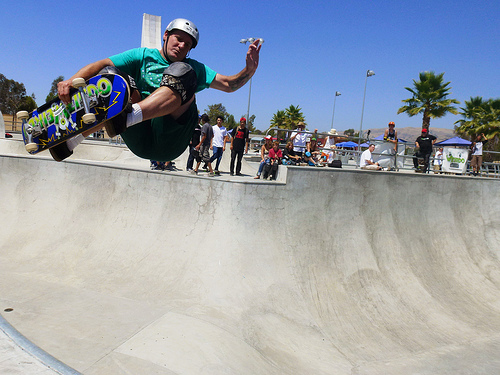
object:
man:
[47, 16, 263, 163]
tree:
[397, 68, 460, 159]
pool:
[0, 153, 497, 374]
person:
[203, 113, 230, 175]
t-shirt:
[210, 122, 228, 148]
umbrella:
[436, 136, 475, 147]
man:
[228, 115, 250, 176]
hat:
[238, 116, 244, 122]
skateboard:
[12, 71, 131, 154]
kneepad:
[158, 59, 198, 102]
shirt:
[108, 44, 216, 100]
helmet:
[163, 18, 200, 48]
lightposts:
[358, 67, 375, 136]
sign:
[440, 145, 470, 178]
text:
[445, 153, 466, 164]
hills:
[353, 121, 457, 146]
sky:
[2, 0, 500, 134]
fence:
[261, 127, 498, 184]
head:
[159, 19, 200, 60]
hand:
[246, 40, 261, 68]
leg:
[129, 60, 199, 138]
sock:
[124, 102, 143, 132]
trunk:
[420, 111, 433, 135]